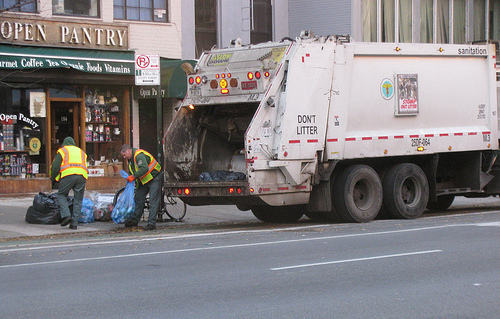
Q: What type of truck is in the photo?
A: Garbage.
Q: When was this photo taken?
A: During the day.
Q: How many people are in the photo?
A: 2.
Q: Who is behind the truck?
A: The men.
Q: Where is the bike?
A: Leaning against a sign.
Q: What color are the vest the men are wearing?
A: Yellow and orange.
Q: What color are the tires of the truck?
A: Black.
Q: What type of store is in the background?
A: Open pantry.